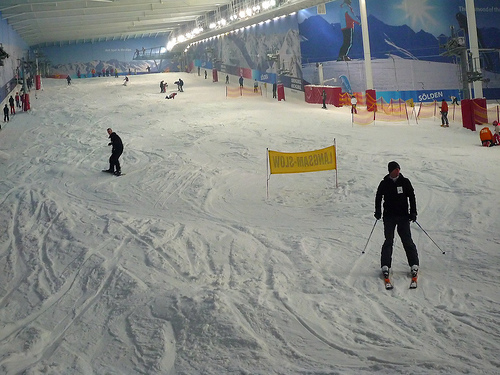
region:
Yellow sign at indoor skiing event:
[265, 138, 340, 178]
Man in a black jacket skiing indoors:
[363, 155, 449, 297]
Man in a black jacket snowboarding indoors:
[96, 122, 128, 173]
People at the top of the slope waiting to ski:
[65, 62, 161, 77]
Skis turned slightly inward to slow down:
[371, 256, 422, 293]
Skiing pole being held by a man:
[406, 217, 451, 257]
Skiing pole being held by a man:
[357, 212, 377, 262]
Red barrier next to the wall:
[300, 82, 341, 110]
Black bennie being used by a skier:
[385, 158, 402, 175]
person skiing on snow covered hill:
[345, 157, 455, 302]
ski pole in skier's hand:
[407, 214, 463, 270]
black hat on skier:
[381, 160, 405, 176]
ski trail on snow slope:
[0, 199, 151, 372]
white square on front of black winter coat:
[390, 183, 406, 195]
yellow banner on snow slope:
[255, 135, 355, 199]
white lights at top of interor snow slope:
[152, 2, 299, 61]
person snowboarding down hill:
[95, 120, 136, 181]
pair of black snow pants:
[376, 219, 421, 269]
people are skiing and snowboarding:
[7, 6, 484, 298]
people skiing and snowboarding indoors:
[22, 38, 451, 328]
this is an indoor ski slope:
[5, 29, 477, 371]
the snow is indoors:
[1, 49, 498, 365]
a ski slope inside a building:
[18, 30, 497, 361]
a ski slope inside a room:
[7, 34, 494, 374]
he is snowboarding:
[86, 105, 138, 182]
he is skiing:
[356, 138, 456, 294]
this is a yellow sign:
[255, 120, 354, 194]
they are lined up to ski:
[5, 59, 37, 135]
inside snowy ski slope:
[0, 0, 497, 374]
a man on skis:
[360, 158, 450, 294]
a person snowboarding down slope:
[100, 126, 124, 178]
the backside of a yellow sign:
[263, 135, 342, 200]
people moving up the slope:
[0, 70, 37, 132]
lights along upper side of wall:
[162, 0, 313, 57]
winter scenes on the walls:
[0, 8, 496, 98]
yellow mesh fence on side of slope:
[333, 89, 498, 132]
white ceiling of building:
[0, 0, 240, 53]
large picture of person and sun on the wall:
[331, 0, 441, 65]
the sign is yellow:
[263, 144, 343, 196]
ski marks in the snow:
[9, 67, 495, 372]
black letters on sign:
[267, 151, 339, 174]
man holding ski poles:
[358, 159, 445, 293]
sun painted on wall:
[398, 0, 438, 33]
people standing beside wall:
[1, 67, 38, 124]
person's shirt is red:
[436, 94, 453, 113]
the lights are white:
[153, 3, 296, 57]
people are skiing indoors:
[0, 0, 499, 371]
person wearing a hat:
[361, 156, 449, 293]